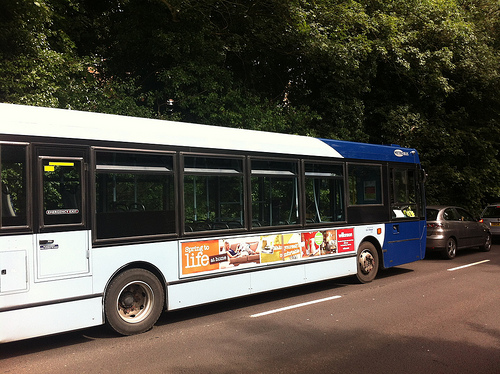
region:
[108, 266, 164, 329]
one bus tire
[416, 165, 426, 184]
the rearview mirror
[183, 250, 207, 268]
the word Life in white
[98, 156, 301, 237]
three passengers window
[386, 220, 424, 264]
this part of the bus is blue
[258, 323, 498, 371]
the shadow of a tree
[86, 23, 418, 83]
a dense forest in the background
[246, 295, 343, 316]
a white line on the pavement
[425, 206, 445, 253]
the rear view of the car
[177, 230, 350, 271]
an Ad sign on the bus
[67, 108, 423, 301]
blue and white bus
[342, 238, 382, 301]
brown wheels on bus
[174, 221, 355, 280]
advert on side of bus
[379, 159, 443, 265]
blue door on bus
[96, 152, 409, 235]
black windows on bus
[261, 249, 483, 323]
white lines on road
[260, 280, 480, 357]
road is brownish grey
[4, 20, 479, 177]
green and leafy trees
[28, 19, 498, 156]
thick stand of trees behind bus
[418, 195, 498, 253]
silver car in front of bus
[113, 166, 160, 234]
window on the bus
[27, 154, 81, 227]
window on the bus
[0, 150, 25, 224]
window on the bus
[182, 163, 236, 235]
window on the bus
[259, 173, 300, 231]
window on the bus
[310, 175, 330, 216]
window on the bus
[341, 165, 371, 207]
window on the bus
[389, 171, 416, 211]
window on the bus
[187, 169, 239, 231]
window on the bus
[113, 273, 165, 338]
wheel on the bus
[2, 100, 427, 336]
a bus stopped in traffic during the day.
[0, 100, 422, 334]
a bus stopped in traffic during the day.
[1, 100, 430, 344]
blue and white passenger bus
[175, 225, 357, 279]
advertisements on the side of the bus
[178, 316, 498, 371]
shadow of a tree on the road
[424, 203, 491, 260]
4 door silver compact car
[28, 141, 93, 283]
emergency exit on a bus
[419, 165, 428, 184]
rear view mirror is black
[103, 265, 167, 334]
large tire with rusted hubcap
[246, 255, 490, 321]
white lane divider lines painted on the ground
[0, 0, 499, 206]
several large trees line the side of the road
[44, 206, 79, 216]
emergency exit sign on bus window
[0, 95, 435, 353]
A white and blue bus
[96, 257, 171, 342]
A round rubber bus tire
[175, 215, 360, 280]
A sign on the side of a bus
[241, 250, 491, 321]
Two white lines on the road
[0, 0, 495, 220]
Green leaves on many trees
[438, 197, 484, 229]
Side windows of a car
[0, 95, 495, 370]
Vehicles driving on the road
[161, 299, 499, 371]
Shadows on the road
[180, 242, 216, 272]
"life" written on orange sign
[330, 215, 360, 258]
White writing on red sign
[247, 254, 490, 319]
Two white stripes painted on a black road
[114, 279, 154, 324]
White rear wheel of a bus with lots of rust in the center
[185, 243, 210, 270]
The words Spring to life in white lettering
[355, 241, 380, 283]
Wheel and tire of a bus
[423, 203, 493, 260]
Silver car parked on a road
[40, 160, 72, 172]
Two yellow stickers placed on a window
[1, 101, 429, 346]
White and blue bus parked on a street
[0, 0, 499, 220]
Lush green leaves of mature trees